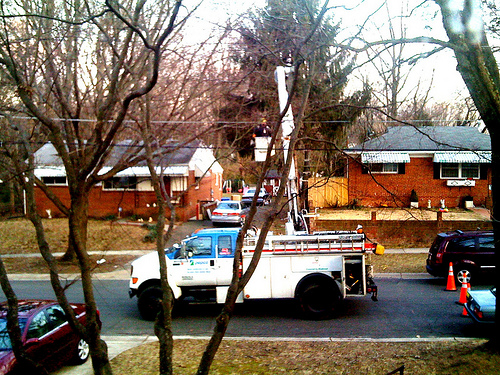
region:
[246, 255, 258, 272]
part of a branch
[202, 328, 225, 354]
edge of a bramch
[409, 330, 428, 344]
edge of a road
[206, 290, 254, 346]
aprt of a tree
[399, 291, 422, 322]
part of a road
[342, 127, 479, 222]
a red brick house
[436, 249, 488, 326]
orange and white safety cones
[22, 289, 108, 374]
a car parked in a driveway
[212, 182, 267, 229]
two cars parked in a driveway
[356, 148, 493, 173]
white and green awnings on a house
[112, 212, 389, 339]
a white and blue work truck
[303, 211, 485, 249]
a red brick fence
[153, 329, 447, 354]
a curb next to a street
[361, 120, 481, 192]
a house with a shingled roof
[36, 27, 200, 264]
a tree with no leaves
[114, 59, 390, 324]
a white crane on a truck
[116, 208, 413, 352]
a truck on the road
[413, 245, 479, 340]
three orange cones blocking a street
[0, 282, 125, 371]
a red car on side the road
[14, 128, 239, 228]
a red house with black roof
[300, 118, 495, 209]
a red house with black roof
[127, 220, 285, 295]
cabin of truck is blue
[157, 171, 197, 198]
window of house is covered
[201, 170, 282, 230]
two cars on a driveway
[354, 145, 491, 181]
two awnings over windows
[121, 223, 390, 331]
truck on a street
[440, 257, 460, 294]
traffic cone on a street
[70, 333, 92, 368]
rear wheel on a car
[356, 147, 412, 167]
awning above a window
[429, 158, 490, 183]
window on a building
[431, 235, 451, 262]
rear tail light on a vehicle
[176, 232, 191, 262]
side rear view mirror on a vehicle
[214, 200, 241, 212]
rear window on a vehicle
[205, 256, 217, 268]
door handle on a vehicle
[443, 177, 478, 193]
flower box below a window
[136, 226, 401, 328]
the truck is white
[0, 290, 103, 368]
the car is red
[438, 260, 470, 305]
the cones are orange and white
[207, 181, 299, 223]
the two cars are parked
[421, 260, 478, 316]
the corns are three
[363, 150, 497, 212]
the wall is red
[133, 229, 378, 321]
the service truck has stopped on the road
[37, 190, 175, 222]
the walls are red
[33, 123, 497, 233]
the two houses are beside the road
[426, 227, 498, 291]
the car is purple